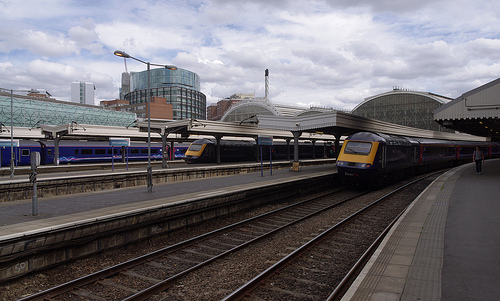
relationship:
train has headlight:
[331, 127, 498, 189] [333, 159, 368, 168]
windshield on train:
[341, 139, 377, 155] [331, 127, 498, 189]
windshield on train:
[341, 139, 377, 155] [181, 135, 434, 166]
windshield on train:
[341, 139, 377, 155] [1, 139, 330, 166]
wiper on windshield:
[348, 140, 386, 150] [336, 121, 438, 172]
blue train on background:
[0, 140, 185, 164] [2, 3, 332, 237]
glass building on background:
[115, 70, 209, 122] [9, 54, 498, 140]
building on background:
[176, 32, 422, 154] [4, 64, 498, 154]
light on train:
[363, 161, 368, 167] [335, 132, 486, 179]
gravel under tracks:
[305, 216, 358, 253] [9, 149, 337, 298]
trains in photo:
[174, 130, 496, 175] [3, 6, 494, 298]